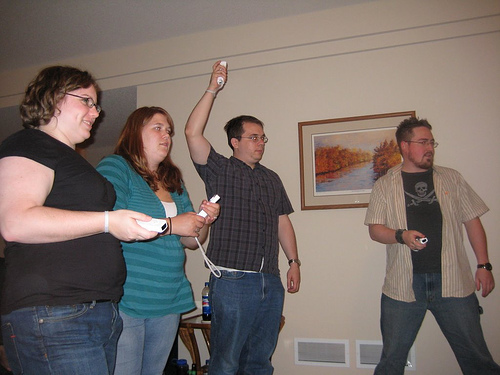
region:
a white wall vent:
[296, 334, 350, 366]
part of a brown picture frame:
[287, 110, 418, 217]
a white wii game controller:
[188, 194, 223, 221]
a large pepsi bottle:
[197, 281, 213, 321]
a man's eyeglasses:
[410, 134, 442, 151]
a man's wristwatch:
[286, 253, 305, 269]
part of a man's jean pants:
[200, 268, 286, 373]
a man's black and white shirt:
[398, 173, 441, 266]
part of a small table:
[178, 311, 290, 366]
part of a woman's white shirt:
[158, 199, 177, 219]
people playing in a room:
[5, 6, 499, 370]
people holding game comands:
[7, 10, 499, 373]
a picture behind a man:
[289, 103, 458, 220]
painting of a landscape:
[288, 97, 431, 225]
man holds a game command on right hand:
[355, 107, 496, 372]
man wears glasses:
[360, 105, 495, 366]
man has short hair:
[352, 110, 487, 230]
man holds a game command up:
[177, 40, 317, 365]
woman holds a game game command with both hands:
[105, 97, 226, 278]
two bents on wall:
[286, 329, 425, 374]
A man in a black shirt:
[366, 116, 496, 373]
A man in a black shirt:
[183, 58, 299, 373]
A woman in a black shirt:
[0, 62, 160, 374]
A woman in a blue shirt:
[96, 103, 220, 373]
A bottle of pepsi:
[199, 281, 212, 318]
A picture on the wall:
[295, 109, 418, 211]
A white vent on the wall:
[353, 335, 418, 368]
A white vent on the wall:
[293, 335, 348, 368]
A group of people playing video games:
[3, 60, 498, 374]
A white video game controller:
[133, 215, 168, 232]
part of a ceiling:
[171, 1, 194, 17]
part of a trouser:
[208, 298, 245, 360]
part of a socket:
[315, 335, 334, 362]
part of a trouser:
[225, 308, 246, 341]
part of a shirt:
[233, 240, 260, 266]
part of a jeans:
[223, 333, 242, 367]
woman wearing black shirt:
[0, 127, 132, 371]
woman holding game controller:
[88, 192, 173, 244]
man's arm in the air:
[164, 15, 245, 173]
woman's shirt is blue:
[99, 149, 211, 314]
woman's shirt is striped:
[88, 150, 221, 318]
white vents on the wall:
[280, 325, 426, 372]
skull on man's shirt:
[398, 175, 437, 214]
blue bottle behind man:
[195, 274, 223, 319]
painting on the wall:
[291, 104, 430, 211]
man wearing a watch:
[279, 245, 304, 273]